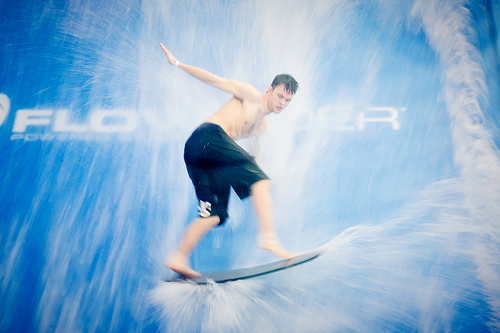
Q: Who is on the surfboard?
A: The man.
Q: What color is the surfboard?
A: Black.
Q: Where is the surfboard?
A: Under the man.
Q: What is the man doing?
A: Surfing.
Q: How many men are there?
A: One.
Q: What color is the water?
A: White.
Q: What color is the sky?
A: Blue.